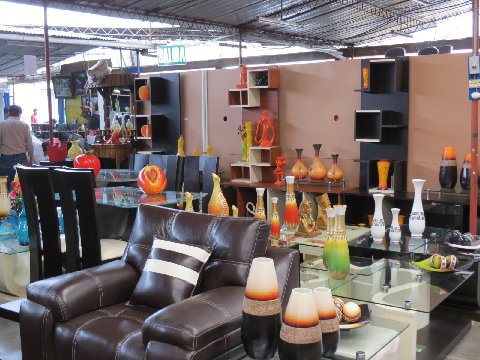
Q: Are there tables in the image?
A: Yes, there is a table.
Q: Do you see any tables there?
A: Yes, there is a table.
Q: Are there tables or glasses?
A: Yes, there is a table.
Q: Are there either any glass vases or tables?
A: Yes, there is a glass table.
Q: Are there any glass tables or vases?
A: Yes, there is a glass table.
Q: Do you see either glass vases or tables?
A: Yes, there is a glass table.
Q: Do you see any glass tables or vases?
A: Yes, there is a glass table.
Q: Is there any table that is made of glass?
A: Yes, there is a table that is made of glass.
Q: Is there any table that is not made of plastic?
A: Yes, there is a table that is made of glass.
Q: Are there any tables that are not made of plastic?
A: Yes, there is a table that is made of glass.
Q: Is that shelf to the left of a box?
A: No, the shelf is to the left of the vase.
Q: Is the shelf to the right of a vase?
A: No, the shelf is to the left of a vase.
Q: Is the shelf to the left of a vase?
A: Yes, the shelf is to the left of a vase.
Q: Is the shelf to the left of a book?
A: No, the shelf is to the left of a vase.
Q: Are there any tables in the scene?
A: Yes, there is a table.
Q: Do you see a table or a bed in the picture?
A: Yes, there is a table.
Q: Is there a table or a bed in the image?
A: Yes, there is a table.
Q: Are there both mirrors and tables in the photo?
A: No, there is a table but no mirrors.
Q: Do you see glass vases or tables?
A: Yes, there is a glass table.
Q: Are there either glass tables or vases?
A: Yes, there is a glass table.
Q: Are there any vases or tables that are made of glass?
A: Yes, the table is made of glass.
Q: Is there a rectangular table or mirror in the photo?
A: Yes, there is a rectangular table.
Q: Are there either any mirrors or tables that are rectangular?
A: Yes, the table is rectangular.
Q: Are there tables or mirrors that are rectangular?
A: Yes, the table is rectangular.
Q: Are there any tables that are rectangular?
A: Yes, there is a rectangular table.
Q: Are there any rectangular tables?
A: Yes, there is a rectangular table.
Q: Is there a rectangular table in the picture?
A: Yes, there is a rectangular table.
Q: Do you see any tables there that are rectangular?
A: Yes, there is a table that is rectangular.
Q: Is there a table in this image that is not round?
A: Yes, there is a rectangular table.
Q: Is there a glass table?
A: Yes, there is a table that is made of glass.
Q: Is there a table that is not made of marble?
A: Yes, there is a table that is made of glass.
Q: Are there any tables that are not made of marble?
A: Yes, there is a table that is made of glass.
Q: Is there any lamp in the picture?
A: No, there are no lamps.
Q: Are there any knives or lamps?
A: No, there are no lamps or knives.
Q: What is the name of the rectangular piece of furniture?
A: The piece of furniture is a table.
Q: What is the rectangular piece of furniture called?
A: The piece of furniture is a table.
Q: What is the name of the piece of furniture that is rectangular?
A: The piece of furniture is a table.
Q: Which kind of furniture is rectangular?
A: The furniture is a table.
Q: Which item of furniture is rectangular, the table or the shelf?
A: The table is rectangular.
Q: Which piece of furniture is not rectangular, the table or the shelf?
A: The shelf is not rectangular.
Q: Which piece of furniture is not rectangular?
A: The piece of furniture is a shelf.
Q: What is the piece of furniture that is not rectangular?
A: The piece of furniture is a shelf.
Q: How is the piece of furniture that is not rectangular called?
A: The piece of furniture is a shelf.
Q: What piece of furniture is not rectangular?
A: The piece of furniture is a shelf.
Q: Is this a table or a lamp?
A: This is a table.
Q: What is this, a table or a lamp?
A: This is a table.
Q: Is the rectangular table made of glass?
A: Yes, the table is made of glass.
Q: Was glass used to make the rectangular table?
A: Yes, the table is made of glass.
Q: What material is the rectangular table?
A: The table is made of glass.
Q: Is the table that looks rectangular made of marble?
A: No, the table is made of glass.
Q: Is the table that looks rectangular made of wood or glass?
A: The table is made of glass.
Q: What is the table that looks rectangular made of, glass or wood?
A: The table is made of glass.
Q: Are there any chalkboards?
A: No, there are no chalkboards.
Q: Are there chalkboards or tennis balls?
A: No, there are no chalkboards or tennis balls.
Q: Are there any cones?
A: No, there are no cones.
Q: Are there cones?
A: No, there are no cones.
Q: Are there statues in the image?
A: No, there are no statues.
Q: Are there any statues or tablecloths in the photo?
A: No, there are no statues or tablecloths.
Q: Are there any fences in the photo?
A: No, there are no fences.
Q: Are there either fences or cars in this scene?
A: No, there are no fences or cars.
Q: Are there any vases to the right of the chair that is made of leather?
A: Yes, there is a vase to the right of the chair.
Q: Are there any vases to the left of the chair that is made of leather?
A: No, the vase is to the right of the chair.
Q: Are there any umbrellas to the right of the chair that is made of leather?
A: No, there is a vase to the right of the chair.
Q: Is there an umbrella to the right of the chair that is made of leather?
A: No, there is a vase to the right of the chair.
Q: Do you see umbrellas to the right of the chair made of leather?
A: No, there is a vase to the right of the chair.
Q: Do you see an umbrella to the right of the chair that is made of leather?
A: No, there is a vase to the right of the chair.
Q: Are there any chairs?
A: Yes, there is a chair.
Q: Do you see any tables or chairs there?
A: Yes, there is a chair.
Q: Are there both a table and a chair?
A: Yes, there are both a chair and a table.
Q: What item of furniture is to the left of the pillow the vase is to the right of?
A: The piece of furniture is a chair.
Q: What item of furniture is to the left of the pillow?
A: The piece of furniture is a chair.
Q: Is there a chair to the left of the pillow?
A: Yes, there is a chair to the left of the pillow.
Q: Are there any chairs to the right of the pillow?
A: No, the chair is to the left of the pillow.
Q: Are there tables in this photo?
A: Yes, there is a table.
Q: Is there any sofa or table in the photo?
A: Yes, there is a table.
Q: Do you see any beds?
A: No, there are no beds.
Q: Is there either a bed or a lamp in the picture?
A: No, there are no beds or lamps.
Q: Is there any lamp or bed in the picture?
A: No, there are no beds or lamps.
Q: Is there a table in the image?
A: Yes, there is a table.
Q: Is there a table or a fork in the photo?
A: Yes, there is a table.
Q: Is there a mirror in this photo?
A: No, there are no mirrors.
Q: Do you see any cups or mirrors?
A: No, there are no mirrors or cups.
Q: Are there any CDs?
A: No, there are no cds.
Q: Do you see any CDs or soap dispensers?
A: No, there are no CDs or soap dispensers.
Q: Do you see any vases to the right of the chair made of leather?
A: Yes, there is a vase to the right of the chair.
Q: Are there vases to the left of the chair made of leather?
A: No, the vase is to the right of the chair.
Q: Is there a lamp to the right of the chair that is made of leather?
A: No, there is a vase to the right of the chair.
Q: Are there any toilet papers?
A: No, there are no toilet papers.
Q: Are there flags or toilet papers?
A: No, there are no toilet papers or flags.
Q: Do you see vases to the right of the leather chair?
A: Yes, there is a vase to the right of the chair.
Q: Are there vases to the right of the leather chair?
A: Yes, there is a vase to the right of the chair.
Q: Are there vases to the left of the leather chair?
A: No, the vase is to the right of the chair.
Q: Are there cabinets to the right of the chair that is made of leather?
A: No, there is a vase to the right of the chair.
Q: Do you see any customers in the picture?
A: No, there are no customers.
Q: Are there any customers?
A: No, there are no customers.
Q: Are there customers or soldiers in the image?
A: No, there are no customers or soldiers.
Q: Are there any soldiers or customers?
A: No, there are no customers or soldiers.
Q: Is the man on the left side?
A: Yes, the man is on the left of the image.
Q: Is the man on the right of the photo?
A: No, the man is on the left of the image.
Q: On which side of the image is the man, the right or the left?
A: The man is on the left of the image.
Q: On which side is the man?
A: The man is on the left of the image.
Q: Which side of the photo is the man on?
A: The man is on the left of the image.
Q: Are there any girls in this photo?
A: No, there are no girls.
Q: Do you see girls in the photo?
A: No, there are no girls.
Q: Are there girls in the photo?
A: No, there are no girls.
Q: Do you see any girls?
A: No, there are no girls.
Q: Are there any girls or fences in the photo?
A: No, there are no girls or fences.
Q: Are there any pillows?
A: Yes, there is a pillow.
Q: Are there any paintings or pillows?
A: Yes, there is a pillow.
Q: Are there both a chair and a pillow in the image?
A: Yes, there are both a pillow and a chair.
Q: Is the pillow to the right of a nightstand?
A: No, the pillow is to the right of the chair.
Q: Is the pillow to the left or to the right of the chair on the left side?
A: The pillow is to the right of the chair.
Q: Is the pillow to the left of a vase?
A: Yes, the pillow is to the left of a vase.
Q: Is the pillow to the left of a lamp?
A: No, the pillow is to the left of a vase.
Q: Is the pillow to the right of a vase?
A: No, the pillow is to the left of a vase.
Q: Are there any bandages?
A: No, there are no bandages.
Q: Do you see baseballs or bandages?
A: No, there are no bandages or baseballs.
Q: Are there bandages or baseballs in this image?
A: No, there are no bandages or baseballs.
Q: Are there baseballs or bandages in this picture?
A: No, there are no bandages or baseballs.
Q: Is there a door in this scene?
A: Yes, there is a door.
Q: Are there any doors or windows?
A: Yes, there is a door.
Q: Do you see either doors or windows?
A: Yes, there is a door.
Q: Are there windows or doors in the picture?
A: Yes, there is a door.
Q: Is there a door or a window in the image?
A: Yes, there is a door.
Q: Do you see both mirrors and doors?
A: No, there is a door but no mirrors.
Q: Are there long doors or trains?
A: Yes, there is a long door.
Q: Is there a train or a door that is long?
A: Yes, the door is long.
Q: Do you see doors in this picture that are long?
A: Yes, there is a long door.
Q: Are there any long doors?
A: Yes, there is a long door.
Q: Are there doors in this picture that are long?
A: Yes, there is a door that is long.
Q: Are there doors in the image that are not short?
A: Yes, there is a long door.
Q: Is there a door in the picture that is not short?
A: Yes, there is a long door.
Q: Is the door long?
A: Yes, the door is long.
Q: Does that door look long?
A: Yes, the door is long.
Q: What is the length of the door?
A: The door is long.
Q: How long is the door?
A: The door is long.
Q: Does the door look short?
A: No, the door is long.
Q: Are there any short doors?
A: No, there is a door but it is long.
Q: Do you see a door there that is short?
A: No, there is a door but it is long.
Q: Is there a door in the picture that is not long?
A: No, there is a door but it is long.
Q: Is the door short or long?
A: The door is long.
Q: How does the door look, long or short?
A: The door is long.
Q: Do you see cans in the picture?
A: No, there are no cans.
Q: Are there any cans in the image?
A: No, there are no cans.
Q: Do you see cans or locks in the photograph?
A: No, there are no cans or locks.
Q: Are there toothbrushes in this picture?
A: No, there are no toothbrushes.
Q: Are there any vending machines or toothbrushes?
A: No, there are no toothbrushes or vending machines.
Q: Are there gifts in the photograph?
A: No, there are no gifts.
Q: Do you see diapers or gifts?
A: No, there are no gifts or diapers.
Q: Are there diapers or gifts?
A: No, there are no gifts or diapers.